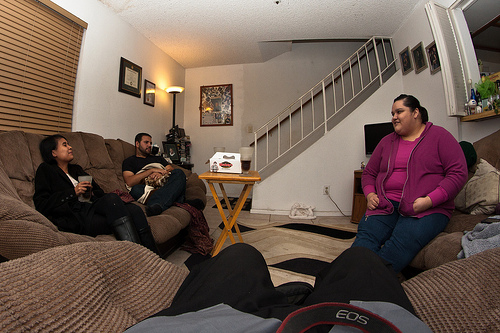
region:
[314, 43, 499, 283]
a women wearing a purple shirt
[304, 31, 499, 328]
a women wearing a purple jacket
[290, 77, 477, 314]
a women wearing jeans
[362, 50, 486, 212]
a women wearing a purple pony tail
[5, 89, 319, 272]
two people sitting on couch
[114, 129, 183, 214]
a man sitting on couch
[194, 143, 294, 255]
a brown small table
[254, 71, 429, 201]
a set of stairs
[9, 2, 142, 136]
a brown window curtain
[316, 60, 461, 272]
a women with purple shirt sitting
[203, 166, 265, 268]
foldable wood table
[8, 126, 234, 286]
the soffa is brown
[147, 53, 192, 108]
light reflection on the wall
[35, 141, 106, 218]
woman holding a glass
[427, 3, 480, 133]
white shutter on the wall opening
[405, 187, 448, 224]
woman has her left hand in pocket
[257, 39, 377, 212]
metal stair railing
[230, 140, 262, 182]
a glass on the table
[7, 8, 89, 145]
blinds on the window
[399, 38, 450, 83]
three pictures on the wall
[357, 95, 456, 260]
girl in purple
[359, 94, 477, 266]
girlsitting down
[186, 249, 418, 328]
a man's knees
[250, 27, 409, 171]
an upstairs staircase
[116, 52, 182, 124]
pictures hanging on wall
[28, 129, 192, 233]
couple sitting on couch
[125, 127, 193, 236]
man holding baby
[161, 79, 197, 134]
lamp and lamp pole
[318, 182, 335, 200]
an electrical outlet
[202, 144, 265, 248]
food on dinner tray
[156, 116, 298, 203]
a box of food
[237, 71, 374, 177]
the rails are white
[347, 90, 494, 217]
this woman wears a purple coat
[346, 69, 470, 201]
she has a ponytail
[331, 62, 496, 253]
she is wearing jeans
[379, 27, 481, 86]
three photos on wall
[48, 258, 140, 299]
the couch is brown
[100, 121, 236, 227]
the man wears jeans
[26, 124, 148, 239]
this woman has a cup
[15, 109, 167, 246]
she is wearing boots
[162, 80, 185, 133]
A lit standing lamp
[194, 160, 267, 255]
A wooden tray table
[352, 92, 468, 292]
A woman wearing purple.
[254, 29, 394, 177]
A white staircase bannister.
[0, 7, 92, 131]
a window with brown blinds drawn.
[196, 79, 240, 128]
A framed photograph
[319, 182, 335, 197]
A white wall outlet.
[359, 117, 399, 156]
A black television.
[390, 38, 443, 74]
Three photographs on the wall.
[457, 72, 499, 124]
A crowded window ledge.